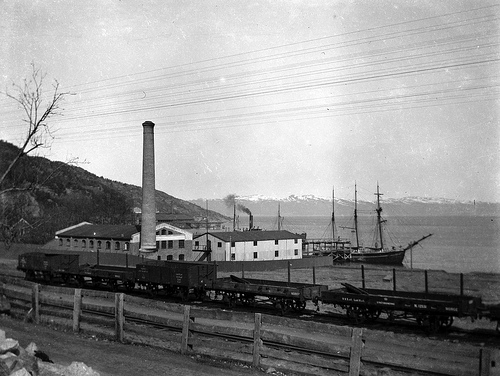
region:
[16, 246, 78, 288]
box car on train rails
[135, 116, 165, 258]
smoke stack for a factory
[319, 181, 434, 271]
sail boat docked at harbor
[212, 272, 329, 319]
flat cart on rail road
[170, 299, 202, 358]
fence post blocking path to rail road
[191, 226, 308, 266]
white factory building with eight windows on facing side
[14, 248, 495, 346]
train carts in a line getting pulled on rail road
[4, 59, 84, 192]
leafless tree jutting twards rail road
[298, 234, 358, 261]
docks going out over the water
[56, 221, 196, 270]
brick factory building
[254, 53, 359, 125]
sunlight splashing across the sky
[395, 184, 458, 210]
snow capped mountain range in the far distance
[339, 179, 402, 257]
tall mast on boat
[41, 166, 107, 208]
tree covered hill top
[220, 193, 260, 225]
smoke coming from smoke stack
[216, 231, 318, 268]
white color on building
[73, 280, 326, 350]
long wooden fence with posts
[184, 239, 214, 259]
steps at side of building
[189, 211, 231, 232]
houses on the hill side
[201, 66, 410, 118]
over head electrical wires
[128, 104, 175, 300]
large brick tower attached to building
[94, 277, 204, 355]
low height wooden fence near the tracks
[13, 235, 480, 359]
cars and caboose of a train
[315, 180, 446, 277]
large boat on the water with no sails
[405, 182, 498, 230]
mountains with snow on the tops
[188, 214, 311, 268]
white building with windows and a roof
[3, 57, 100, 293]
large branch growing off of tree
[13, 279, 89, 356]
fence posts stuck in the dirt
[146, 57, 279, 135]
power lines across the sky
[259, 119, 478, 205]
white clouds in the gray sky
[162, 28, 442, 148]
power lines over the train tracks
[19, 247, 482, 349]
a black train on the tracks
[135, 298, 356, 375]
grey wood fence next to the tracks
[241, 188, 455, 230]
snow capped mountains in the distance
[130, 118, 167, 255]
stone smoke stack of the building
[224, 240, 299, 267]
white wall of the building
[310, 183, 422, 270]
a black sailboat on the water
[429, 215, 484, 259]
calm grey water of the ocean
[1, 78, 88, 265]
leafless grey branches of a tree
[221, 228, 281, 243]
black roof of a building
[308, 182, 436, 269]
large old world sailing vessel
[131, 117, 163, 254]
tall smoke stack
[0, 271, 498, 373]
wooden fence and posts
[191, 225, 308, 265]
long white building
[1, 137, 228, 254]
tall barren rocky hills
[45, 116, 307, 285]
small factory by the water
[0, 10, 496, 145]
many thin black electrical wires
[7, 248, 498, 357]
several black trailers attached together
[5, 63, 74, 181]
leafless black tree branch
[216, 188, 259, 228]
black smoke from a small smoke stack